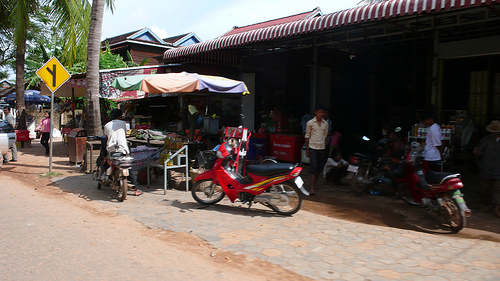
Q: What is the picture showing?
A: It is showing a street.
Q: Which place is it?
A: It is a street.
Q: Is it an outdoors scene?
A: Yes, it is outdoors.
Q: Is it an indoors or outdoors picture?
A: It is outdoors.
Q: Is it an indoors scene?
A: No, it is outdoors.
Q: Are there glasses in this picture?
A: No, there are no glasses.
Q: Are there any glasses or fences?
A: No, there are no glasses or fences.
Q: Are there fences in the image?
A: No, there are no fences.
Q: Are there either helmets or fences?
A: No, there are no fences or helmets.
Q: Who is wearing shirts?
A: The man is wearing shirts.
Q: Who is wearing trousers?
A: The man is wearing trousers.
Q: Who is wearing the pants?
A: The man is wearing trousers.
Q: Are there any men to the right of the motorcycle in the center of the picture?
A: Yes, there is a man to the right of the motorcycle.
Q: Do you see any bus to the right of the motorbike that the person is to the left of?
A: No, there is a man to the right of the motorbike.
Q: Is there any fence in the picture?
A: No, there are no fences.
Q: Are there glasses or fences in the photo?
A: No, there are no fences or glasses.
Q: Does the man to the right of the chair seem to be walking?
A: Yes, the man is walking.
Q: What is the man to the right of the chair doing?
A: The man is walking.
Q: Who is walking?
A: The man is walking.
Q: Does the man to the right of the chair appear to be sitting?
A: No, the man is walking.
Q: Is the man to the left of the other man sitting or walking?
A: The man is walking.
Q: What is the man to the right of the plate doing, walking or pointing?
A: The man is walking.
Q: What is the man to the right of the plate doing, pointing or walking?
A: The man is walking.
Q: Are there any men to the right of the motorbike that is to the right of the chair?
A: Yes, there is a man to the right of the motorcycle.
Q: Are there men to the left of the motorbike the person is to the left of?
A: No, the man is to the right of the motorcycle.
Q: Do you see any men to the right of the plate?
A: Yes, there is a man to the right of the plate.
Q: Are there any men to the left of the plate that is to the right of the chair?
A: No, the man is to the right of the plate.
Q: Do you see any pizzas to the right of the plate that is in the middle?
A: No, there is a man to the right of the plate.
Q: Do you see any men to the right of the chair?
A: Yes, there is a man to the right of the chair.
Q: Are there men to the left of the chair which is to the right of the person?
A: No, the man is to the right of the chair.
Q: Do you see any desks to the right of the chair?
A: No, there is a man to the right of the chair.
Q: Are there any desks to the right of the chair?
A: No, there is a man to the right of the chair.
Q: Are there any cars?
A: No, there are no cars.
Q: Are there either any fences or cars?
A: No, there are no cars or fences.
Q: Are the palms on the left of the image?
A: Yes, the palms are on the left of the image.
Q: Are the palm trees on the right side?
A: No, the palm trees are on the left of the image.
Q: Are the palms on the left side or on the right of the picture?
A: The palms are on the left of the image.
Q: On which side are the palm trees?
A: The palm trees are on the left of the image.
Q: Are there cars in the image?
A: No, there are no cars.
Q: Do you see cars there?
A: No, there are no cars.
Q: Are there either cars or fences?
A: No, there are no cars or fences.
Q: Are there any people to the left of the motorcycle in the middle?
A: Yes, there is a person to the left of the motorbike.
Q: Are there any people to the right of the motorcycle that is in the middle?
A: No, the person is to the left of the motorbike.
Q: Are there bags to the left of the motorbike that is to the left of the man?
A: No, there is a person to the left of the motorcycle.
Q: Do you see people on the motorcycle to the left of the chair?
A: Yes, there is a person on the motorcycle.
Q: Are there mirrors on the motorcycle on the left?
A: No, there is a person on the motorcycle.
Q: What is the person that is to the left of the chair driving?
A: The person is driving a motorcycle.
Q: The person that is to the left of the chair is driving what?
A: The person is driving a motorcycle.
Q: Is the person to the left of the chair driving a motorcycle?
A: Yes, the person is driving a motorcycle.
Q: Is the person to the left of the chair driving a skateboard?
A: No, the person is driving a motorcycle.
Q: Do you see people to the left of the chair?
A: Yes, there is a person to the left of the chair.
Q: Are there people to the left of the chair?
A: Yes, there is a person to the left of the chair.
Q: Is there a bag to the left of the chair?
A: No, there is a person to the left of the chair.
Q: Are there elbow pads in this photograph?
A: No, there are no elbow pads.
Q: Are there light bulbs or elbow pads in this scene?
A: No, there are no elbow pads or light bulbs.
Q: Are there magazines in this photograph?
A: No, there are no magazines.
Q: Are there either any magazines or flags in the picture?
A: No, there are no magazines or flags.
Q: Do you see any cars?
A: No, there are no cars.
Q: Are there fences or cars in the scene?
A: No, there are no cars or fences.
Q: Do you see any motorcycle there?
A: Yes, there are motorcycles.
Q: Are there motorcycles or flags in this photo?
A: Yes, there are motorcycles.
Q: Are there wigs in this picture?
A: No, there are no wigs.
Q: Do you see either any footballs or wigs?
A: No, there are no wigs or footballs.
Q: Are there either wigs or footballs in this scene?
A: No, there are no wigs or footballs.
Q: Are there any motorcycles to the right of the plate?
A: Yes, there are motorcycles to the right of the plate.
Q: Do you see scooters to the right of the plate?
A: No, there are motorcycles to the right of the plate.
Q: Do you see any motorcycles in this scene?
A: Yes, there is a motorcycle.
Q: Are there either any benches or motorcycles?
A: Yes, there is a motorcycle.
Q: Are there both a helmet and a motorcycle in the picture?
A: No, there is a motorcycle but no helmets.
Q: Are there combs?
A: No, there are no combs.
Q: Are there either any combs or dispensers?
A: No, there are no combs or dispensers.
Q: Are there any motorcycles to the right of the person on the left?
A: Yes, there is a motorcycle to the right of the person.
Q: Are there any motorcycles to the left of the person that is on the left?
A: No, the motorcycle is to the right of the person.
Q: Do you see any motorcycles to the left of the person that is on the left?
A: No, the motorcycle is to the right of the person.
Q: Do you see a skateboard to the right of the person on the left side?
A: No, there is a motorcycle to the right of the person.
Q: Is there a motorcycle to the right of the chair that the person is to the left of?
A: Yes, there is a motorcycle to the right of the chair.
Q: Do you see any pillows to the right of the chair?
A: No, there is a motorcycle to the right of the chair.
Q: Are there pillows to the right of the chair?
A: No, there is a motorcycle to the right of the chair.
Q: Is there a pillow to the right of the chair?
A: No, there is a motorcycle to the right of the chair.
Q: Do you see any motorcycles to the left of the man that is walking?
A: Yes, there is a motorcycle to the left of the man.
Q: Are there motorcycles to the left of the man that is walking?
A: Yes, there is a motorcycle to the left of the man.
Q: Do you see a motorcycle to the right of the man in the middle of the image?
A: No, the motorcycle is to the left of the man.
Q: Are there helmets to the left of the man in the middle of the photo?
A: No, there is a motorcycle to the left of the man.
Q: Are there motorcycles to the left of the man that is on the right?
A: Yes, there is a motorcycle to the left of the man.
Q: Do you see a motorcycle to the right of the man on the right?
A: No, the motorcycle is to the left of the man.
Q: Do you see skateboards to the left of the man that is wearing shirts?
A: No, there is a motorcycle to the left of the man.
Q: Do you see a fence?
A: No, there are no fences.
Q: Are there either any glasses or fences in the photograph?
A: No, there are no fences or glasses.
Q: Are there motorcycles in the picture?
A: Yes, there is a motorcycle.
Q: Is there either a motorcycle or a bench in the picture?
A: Yes, there is a motorcycle.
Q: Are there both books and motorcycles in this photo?
A: No, there is a motorcycle but no books.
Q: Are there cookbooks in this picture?
A: No, there are no cookbooks.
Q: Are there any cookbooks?
A: No, there are no cookbooks.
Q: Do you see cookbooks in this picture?
A: No, there are no cookbooks.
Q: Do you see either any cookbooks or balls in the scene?
A: No, there are no cookbooks or balls.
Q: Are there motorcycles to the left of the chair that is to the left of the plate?
A: Yes, there is a motorcycle to the left of the chair.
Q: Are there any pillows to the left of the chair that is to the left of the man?
A: No, there is a motorcycle to the left of the chair.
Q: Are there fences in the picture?
A: No, there are no fences.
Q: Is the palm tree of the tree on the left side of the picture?
A: Yes, the palm tree is on the left of the image.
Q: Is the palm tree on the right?
A: No, the palm tree is on the left of the image.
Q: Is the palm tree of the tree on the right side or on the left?
A: The palm is on the left of the image.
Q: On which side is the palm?
A: The palm is on the left of the image.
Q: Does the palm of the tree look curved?
A: Yes, the palm is curved.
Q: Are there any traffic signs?
A: Yes, there is a traffic sign.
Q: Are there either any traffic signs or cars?
A: Yes, there is a traffic sign.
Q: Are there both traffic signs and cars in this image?
A: No, there is a traffic sign but no cars.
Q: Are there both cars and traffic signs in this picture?
A: No, there is a traffic sign but no cars.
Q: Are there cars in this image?
A: No, there are no cars.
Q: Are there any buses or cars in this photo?
A: No, there are no cars or buses.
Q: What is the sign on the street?
A: The sign is a traffic sign.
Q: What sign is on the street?
A: The sign is a traffic sign.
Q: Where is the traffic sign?
A: The traffic sign is on the street.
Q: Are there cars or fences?
A: No, there are no cars or fences.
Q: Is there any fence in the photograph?
A: No, there are no fences.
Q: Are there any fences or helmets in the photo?
A: No, there are no fences or helmets.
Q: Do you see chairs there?
A: Yes, there is a chair.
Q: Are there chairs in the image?
A: Yes, there is a chair.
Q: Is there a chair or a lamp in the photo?
A: Yes, there is a chair.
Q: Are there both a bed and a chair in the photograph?
A: No, there is a chair but no beds.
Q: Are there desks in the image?
A: No, there are no desks.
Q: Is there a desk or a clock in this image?
A: No, there are no desks or clocks.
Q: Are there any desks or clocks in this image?
A: No, there are no desks or clocks.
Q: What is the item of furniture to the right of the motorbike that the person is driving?
A: The piece of furniture is a chair.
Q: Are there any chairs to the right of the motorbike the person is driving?
A: Yes, there is a chair to the right of the motorbike.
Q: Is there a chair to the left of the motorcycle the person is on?
A: No, the chair is to the right of the motorcycle.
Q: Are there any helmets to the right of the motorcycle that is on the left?
A: No, there is a chair to the right of the motorcycle.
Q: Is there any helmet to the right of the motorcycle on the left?
A: No, there is a chair to the right of the motorcycle.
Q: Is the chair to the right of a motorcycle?
A: Yes, the chair is to the right of a motorcycle.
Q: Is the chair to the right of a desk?
A: No, the chair is to the right of a motorcycle.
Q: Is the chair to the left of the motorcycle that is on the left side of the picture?
A: No, the chair is to the right of the motorcycle.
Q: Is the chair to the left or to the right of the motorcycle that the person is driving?
A: The chair is to the right of the motorbike.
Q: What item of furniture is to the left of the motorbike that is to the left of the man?
A: The piece of furniture is a chair.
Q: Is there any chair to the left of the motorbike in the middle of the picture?
A: Yes, there is a chair to the left of the motorcycle.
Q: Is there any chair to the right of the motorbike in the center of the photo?
A: No, the chair is to the left of the motorcycle.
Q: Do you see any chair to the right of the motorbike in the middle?
A: No, the chair is to the left of the motorcycle.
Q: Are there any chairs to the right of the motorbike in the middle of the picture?
A: No, the chair is to the left of the motorcycle.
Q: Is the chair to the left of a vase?
A: No, the chair is to the left of the motorcycle.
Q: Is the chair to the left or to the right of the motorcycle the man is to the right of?
A: The chair is to the left of the motorcycle.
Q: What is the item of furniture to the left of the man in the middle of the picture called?
A: The piece of furniture is a chair.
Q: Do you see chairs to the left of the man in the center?
A: Yes, there is a chair to the left of the man.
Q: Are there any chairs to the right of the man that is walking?
A: No, the chair is to the left of the man.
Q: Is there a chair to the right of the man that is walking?
A: No, the chair is to the left of the man.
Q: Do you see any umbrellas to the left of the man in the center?
A: No, there is a chair to the left of the man.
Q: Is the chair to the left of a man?
A: Yes, the chair is to the left of a man.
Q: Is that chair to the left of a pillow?
A: No, the chair is to the left of a man.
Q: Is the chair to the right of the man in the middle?
A: No, the chair is to the left of the man.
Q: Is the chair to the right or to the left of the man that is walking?
A: The chair is to the left of the man.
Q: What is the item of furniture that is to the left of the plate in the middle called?
A: The piece of furniture is a chair.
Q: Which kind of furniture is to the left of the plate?
A: The piece of furniture is a chair.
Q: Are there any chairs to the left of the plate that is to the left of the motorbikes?
A: Yes, there is a chair to the left of the plate.